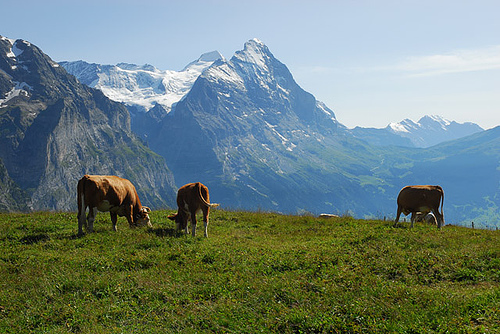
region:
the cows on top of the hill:
[68, 172, 445, 235]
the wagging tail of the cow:
[193, 180, 223, 209]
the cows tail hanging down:
[435, 180, 450, 230]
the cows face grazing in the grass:
[130, 190, 156, 234]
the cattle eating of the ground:
[65, 169, 223, 249]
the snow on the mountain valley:
[0, 41, 30, 104]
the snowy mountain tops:
[0, 33, 274, 95]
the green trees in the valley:
[268, 141, 395, 210]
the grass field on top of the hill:
[128, 232, 498, 329]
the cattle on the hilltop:
[65, 158, 455, 239]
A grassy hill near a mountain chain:
[1, 210, 498, 331]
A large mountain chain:
[0, 37, 499, 210]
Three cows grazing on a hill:
[76, 174, 445, 234]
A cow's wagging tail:
[196, 182, 218, 207]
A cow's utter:
[96, 201, 111, 212]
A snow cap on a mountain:
[58, 48, 225, 110]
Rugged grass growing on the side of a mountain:
[276, 109, 349, 174]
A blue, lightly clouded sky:
[1, 0, 497, 129]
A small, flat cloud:
[375, 50, 499, 81]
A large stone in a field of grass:
[318, 212, 338, 217]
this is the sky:
[315, 22, 355, 34]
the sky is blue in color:
[323, 19, 378, 39]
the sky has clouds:
[359, 59, 474, 79]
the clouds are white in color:
[357, 51, 462, 78]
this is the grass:
[242, 229, 308, 263]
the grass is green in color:
[190, 253, 255, 306]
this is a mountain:
[213, 42, 335, 191]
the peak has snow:
[131, 79, 164, 95]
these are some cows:
[61, 152, 451, 252]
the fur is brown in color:
[110, 178, 127, 193]